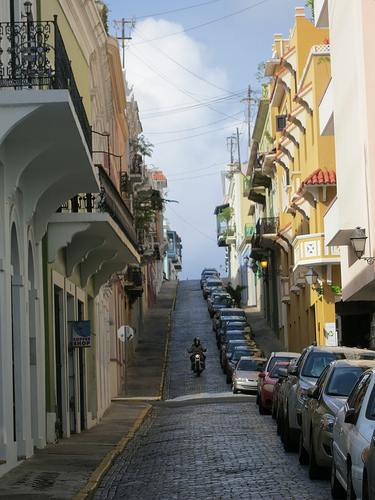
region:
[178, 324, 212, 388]
A motorcycle on a cobblestone street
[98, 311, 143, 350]
The back of a stop sign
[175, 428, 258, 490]
A section of cobblestone street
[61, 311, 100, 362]
A sign for a coffee shop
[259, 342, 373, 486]
Cars parked on a street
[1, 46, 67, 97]
An ornate metal balcony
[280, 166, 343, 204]
A Southwestern style roof area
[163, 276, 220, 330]
A narrow section of a street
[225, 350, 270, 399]
A silver car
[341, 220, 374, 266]
An old-fashioned style street light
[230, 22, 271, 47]
part of the sky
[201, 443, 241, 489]
part of the road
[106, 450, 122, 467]
part of the road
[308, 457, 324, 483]
part of the front wheel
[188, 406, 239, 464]
surface of the road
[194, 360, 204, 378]
part of the front wheel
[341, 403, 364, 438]
part of a side mirror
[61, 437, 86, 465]
part of a walk path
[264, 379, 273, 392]
part of a headlight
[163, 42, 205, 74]
part of some wires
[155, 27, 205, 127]
these are wires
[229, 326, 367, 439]
these are parked vehicles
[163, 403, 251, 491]
this is a road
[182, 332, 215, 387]
this is a motor cycle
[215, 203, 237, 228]
this is a flower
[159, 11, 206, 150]
this is the sky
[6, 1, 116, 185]
this is a building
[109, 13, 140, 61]
this is an electric pole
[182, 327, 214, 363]
the man is ridding a motor cycle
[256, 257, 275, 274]
this is a bulb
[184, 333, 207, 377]
this is a motorist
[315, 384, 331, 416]
this is a vehicle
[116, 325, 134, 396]
this is a post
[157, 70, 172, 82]
these are electrical wires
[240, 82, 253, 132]
this is a pole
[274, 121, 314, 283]
this is a building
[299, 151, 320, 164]
the building is painted brown in color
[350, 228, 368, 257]
this is a lump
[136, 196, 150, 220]
this is a tree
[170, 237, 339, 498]
city street lined with cars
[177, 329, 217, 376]
motorcycle riding down street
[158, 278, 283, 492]
city street made from bricks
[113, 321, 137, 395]
stop sign at street corner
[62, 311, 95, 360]
sign for coffee shop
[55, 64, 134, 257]
balconies on the buildings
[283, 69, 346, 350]
yellow building facing street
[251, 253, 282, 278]
lamp over sidewalk lit up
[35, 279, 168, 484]
empty city sidewalks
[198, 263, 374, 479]
cars all parked on right side of street